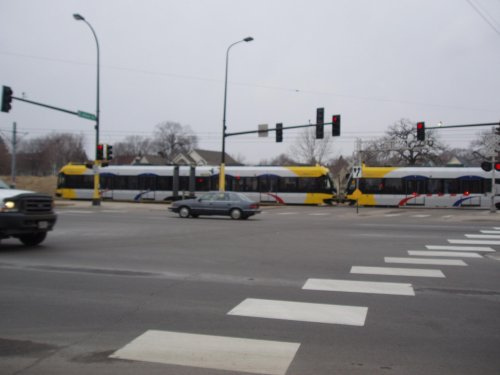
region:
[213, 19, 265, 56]
street light on top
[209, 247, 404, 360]
a white box in road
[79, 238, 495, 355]
a series of white lines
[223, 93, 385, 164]
street signals in road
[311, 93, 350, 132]
red light signals in road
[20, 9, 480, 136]
a beautiful view of sky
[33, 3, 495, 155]
a beautiful view of clouds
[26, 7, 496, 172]
a view of clouds in sky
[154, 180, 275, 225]
a car in the road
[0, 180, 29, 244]
a light working in jeep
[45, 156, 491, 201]
There are two buses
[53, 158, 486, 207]
The trains are white and yellow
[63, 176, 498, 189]
The trains have long windows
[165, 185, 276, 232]
The car is in the middle of the street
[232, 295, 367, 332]
The lines are white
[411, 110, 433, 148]
The traffic signal says stop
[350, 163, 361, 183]
The sign is white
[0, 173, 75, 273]
A truck is coming up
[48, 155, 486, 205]
The train is moving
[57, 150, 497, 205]
the train has two cars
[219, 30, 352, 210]
an electric lamp above the road traffic signal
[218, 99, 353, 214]
the traffic signal is showing its red color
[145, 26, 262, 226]
the car is moving past the lamp post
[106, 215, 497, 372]
white thick stripes representing the zebra cross on the road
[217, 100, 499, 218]
two road traffic signals showing red at the same time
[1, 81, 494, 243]
three traffic signals on the road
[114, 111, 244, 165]
some roofs behind the trees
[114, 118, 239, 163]
trees in front of the roofs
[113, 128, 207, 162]
trees without any leaves in their branches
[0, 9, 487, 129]
the sky is so clear without any clouds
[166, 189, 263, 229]
a grey car on a road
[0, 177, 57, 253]
a truck on a road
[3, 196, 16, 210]
a headlight on a truck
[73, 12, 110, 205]
a light post next to a road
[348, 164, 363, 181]
a black and white street sign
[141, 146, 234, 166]
a house behind a train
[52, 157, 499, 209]
a yellow and white train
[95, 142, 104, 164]
a red stop light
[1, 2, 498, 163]
a gray sky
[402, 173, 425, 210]
a double door on the side of a train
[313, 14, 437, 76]
this is the sky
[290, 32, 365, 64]
the sky is blue in color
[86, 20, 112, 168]
this is a pole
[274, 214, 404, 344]
this is a road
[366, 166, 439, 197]
this is a bus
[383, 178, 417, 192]
this is the windows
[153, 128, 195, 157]
this is a tree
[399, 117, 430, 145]
this is a traffic light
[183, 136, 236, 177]
this is a building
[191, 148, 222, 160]
this is the roof